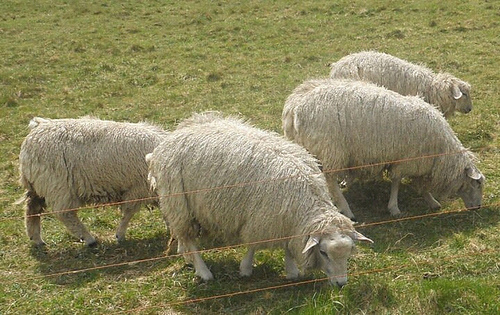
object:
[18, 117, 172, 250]
sheep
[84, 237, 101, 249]
hoove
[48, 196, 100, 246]
leg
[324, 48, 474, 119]
sheep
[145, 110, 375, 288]
sheep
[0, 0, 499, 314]
field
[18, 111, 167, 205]
fluffy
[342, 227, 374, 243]
ear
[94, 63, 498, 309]
eating grass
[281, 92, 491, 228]
sheep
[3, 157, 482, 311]
fence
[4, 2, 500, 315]
grass